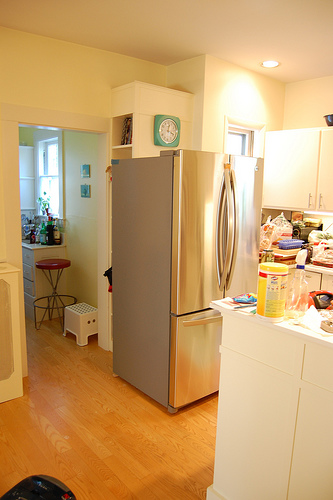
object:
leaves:
[43, 191, 46, 195]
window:
[34, 136, 63, 219]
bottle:
[286, 249, 308, 319]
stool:
[33, 258, 78, 332]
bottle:
[40, 219, 49, 244]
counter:
[22, 240, 61, 249]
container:
[256, 261, 288, 323]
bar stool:
[33, 258, 78, 332]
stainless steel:
[122, 171, 159, 259]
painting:
[80, 164, 91, 179]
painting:
[80, 184, 92, 198]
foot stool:
[63, 302, 99, 347]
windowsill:
[21, 215, 66, 251]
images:
[80, 164, 91, 198]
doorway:
[18, 122, 108, 379]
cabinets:
[261, 126, 333, 213]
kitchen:
[0, 0, 332, 500]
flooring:
[0, 411, 33, 466]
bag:
[259, 211, 293, 252]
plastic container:
[277, 239, 305, 249]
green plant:
[37, 192, 52, 217]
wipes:
[294, 304, 330, 336]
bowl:
[323, 114, 333, 127]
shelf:
[110, 112, 133, 158]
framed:
[154, 114, 180, 147]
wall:
[134, 81, 193, 157]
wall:
[67, 123, 90, 156]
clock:
[154, 114, 181, 147]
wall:
[18, 46, 97, 96]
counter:
[258, 260, 332, 277]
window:
[223, 115, 255, 158]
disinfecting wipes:
[232, 292, 257, 313]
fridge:
[111, 149, 264, 414]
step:
[63, 302, 99, 347]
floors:
[177, 465, 201, 497]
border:
[154, 114, 180, 147]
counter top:
[209, 296, 333, 342]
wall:
[100, 315, 108, 348]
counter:
[205, 292, 332, 500]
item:
[277, 239, 305, 249]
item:
[273, 246, 301, 255]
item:
[309, 249, 333, 269]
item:
[259, 249, 275, 263]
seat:
[36, 259, 72, 270]